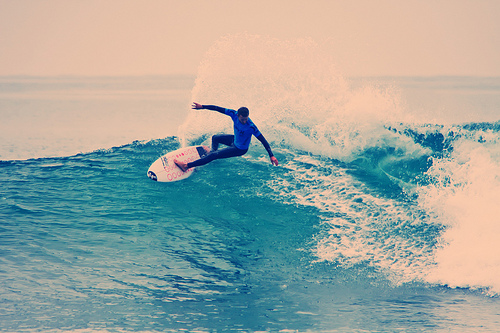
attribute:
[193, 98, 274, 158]
shirt — blue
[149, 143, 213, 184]
surfboard — white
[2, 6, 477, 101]
sky — grey, pink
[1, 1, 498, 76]
skies — cloudy, grey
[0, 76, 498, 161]
water — calm, blue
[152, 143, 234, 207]
surfboard — white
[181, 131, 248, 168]
pants — black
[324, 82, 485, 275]
surf — white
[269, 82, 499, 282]
foam — white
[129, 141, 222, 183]
surboard — white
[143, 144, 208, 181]
surfboard — white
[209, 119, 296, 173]
wetsuit — black, blue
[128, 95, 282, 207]
surfer — male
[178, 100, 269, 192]
wet suit — blue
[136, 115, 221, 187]
surboard spray — white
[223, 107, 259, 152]
shirt — black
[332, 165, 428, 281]
foam — white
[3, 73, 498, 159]
blue waters — calm